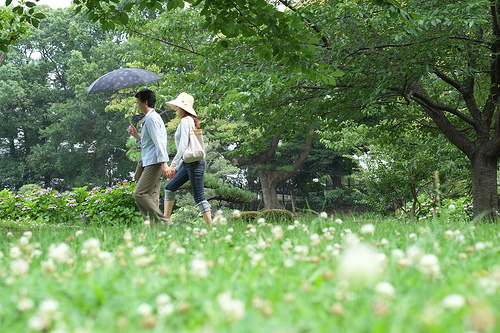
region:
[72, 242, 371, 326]
The grass is green.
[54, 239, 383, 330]
The grass is tall.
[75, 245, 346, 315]
The grass has flowers in it.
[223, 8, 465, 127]
The trees have leaves.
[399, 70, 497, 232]
A tree trunk.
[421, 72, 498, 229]
The tree trunk is gray.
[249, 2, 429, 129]
The leaves are green.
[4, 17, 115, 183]
Trees are in the background.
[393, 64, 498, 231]
The tree trunk is thick.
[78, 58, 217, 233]
Two people are walking.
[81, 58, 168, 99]
a black umbrella over the woman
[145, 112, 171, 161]
the arm of a woman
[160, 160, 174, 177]
the hand of a woman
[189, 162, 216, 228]
the leg of a woman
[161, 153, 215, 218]
a pair of blue jeans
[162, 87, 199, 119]
a hat on the woman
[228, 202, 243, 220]
a white puffy flower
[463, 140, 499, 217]
a brown tree trunk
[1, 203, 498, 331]
a green grassy field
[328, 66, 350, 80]
a green leaf on the tree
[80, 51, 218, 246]
couple walking in the garden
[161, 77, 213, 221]
woman with a straw hat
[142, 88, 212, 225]
woman carrying her purse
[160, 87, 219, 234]
woman with handbag over her shoulder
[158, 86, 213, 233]
woman with her pant rolled up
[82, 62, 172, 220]
person with an umbrella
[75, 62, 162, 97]
umbrella with a pattern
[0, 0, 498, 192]
area with lots of foliage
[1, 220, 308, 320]
white flowers in the foreground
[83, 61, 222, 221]
couple holding hands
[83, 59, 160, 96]
a black umbrella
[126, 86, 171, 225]
a man holding a woman's hand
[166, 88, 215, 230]
a woman carrying a bag on her shoulder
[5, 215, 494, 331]
a field of grass and flowers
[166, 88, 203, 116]
a hat on a woman's head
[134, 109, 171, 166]
a white jacket on a man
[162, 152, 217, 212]
blue jeans on a woman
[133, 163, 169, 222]
brown pants on a man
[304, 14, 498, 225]
a leafy green tree with brown trunk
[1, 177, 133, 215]
a row of bushes with purple flowers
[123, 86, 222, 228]
young couple walking in park and holding hands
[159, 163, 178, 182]
young couple holding hands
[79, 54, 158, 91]
black open umbrella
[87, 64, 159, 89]
black open umbrella held by young person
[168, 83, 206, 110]
young woman wearing white hat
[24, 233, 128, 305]
green grass and white flowers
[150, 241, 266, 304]
green grass and white flowers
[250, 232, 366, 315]
green grass and white flowers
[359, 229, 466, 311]
green grass and white flowers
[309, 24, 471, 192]
brown trees with green leaves